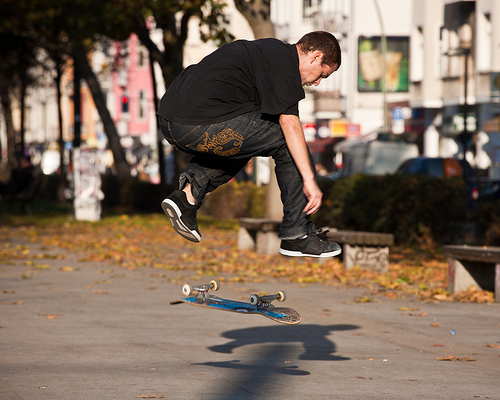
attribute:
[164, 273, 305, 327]
skateboard — blue, in the air, upside down, for skating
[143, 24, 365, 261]
skateboarder — getting air time, doing a trick, in the air, skateboarding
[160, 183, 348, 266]
shoes — black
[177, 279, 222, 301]
truck — upside down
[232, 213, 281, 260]
bench — stone, concrete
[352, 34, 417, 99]
sign — advertisement, notification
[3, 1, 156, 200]
tree — losing leaves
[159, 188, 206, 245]
shoe — black, white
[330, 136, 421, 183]
vehicle — in the distance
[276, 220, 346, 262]
shoe — black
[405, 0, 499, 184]
building — blurry